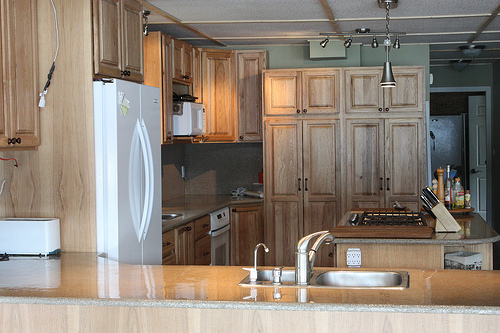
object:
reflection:
[120, 265, 210, 301]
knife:
[419, 187, 439, 220]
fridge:
[91, 76, 164, 266]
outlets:
[345, 247, 362, 267]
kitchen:
[0, 0, 500, 332]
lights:
[318, 30, 405, 49]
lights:
[378, 2, 396, 88]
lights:
[140, 8, 151, 37]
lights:
[458, 44, 487, 58]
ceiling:
[133, 1, 498, 57]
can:
[444, 251, 483, 271]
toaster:
[0, 217, 62, 257]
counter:
[0, 251, 499, 316]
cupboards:
[264, 121, 423, 200]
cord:
[35, 0, 62, 109]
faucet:
[247, 228, 334, 287]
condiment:
[451, 178, 465, 210]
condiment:
[432, 178, 440, 195]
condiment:
[445, 165, 454, 210]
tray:
[420, 203, 474, 215]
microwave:
[172, 93, 207, 136]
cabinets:
[258, 64, 430, 244]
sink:
[238, 267, 407, 292]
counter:
[356, 210, 428, 227]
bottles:
[451, 178, 465, 210]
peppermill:
[435, 168, 445, 205]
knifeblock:
[430, 202, 462, 233]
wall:
[0, 0, 94, 256]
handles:
[129, 116, 158, 241]